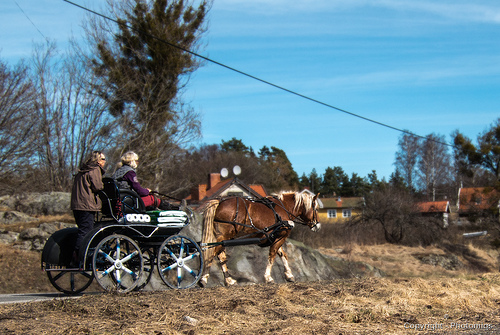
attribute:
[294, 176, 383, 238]
house — yellow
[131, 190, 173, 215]
pants — red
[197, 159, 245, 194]
chimney — brick, taller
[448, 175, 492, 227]
roof — red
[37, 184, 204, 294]
carriage — horse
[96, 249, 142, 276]
spokes — white